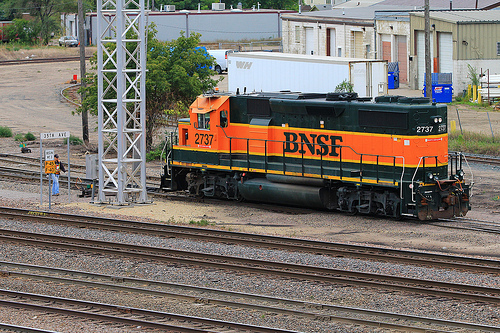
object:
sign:
[22, 132, 89, 168]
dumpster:
[423, 72, 455, 105]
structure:
[93, 0, 153, 207]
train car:
[159, 88, 473, 218]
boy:
[206, 129, 217, 151]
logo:
[284, 132, 343, 157]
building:
[277, 0, 500, 97]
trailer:
[224, 50, 389, 97]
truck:
[224, 50, 387, 100]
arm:
[59, 161, 64, 171]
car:
[160, 87, 469, 220]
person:
[46, 154, 64, 195]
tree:
[59, 27, 218, 152]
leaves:
[159, 57, 167, 64]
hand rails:
[218, 134, 444, 180]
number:
[194, 133, 213, 145]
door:
[180, 128, 188, 146]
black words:
[283, 130, 343, 156]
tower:
[92, 0, 153, 207]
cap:
[54, 154, 59, 158]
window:
[195, 112, 209, 129]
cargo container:
[223, 48, 388, 100]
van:
[207, 49, 229, 73]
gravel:
[163, 233, 245, 258]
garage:
[278, 0, 500, 93]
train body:
[281, 119, 377, 171]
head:
[53, 154, 58, 159]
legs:
[52, 175, 58, 192]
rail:
[0, 206, 496, 327]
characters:
[281, 131, 340, 154]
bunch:
[0, 152, 496, 331]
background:
[0, 0, 500, 216]